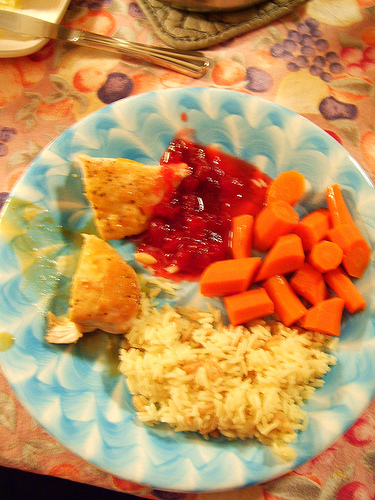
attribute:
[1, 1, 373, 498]
tablecloth — printed, colorful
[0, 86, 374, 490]
plate — blue, white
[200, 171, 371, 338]
carrots — sliced, orange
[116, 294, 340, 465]
rice — white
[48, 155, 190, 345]
chicken — glazed, cut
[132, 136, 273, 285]
cherries — red